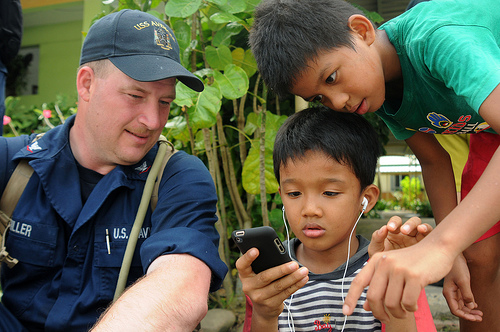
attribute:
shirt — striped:
[277, 238, 382, 328]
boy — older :
[228, 100, 435, 330]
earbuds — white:
[347, 179, 397, 215]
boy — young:
[263, 95, 403, 313]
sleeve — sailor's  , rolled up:
[141, 159, 226, 286]